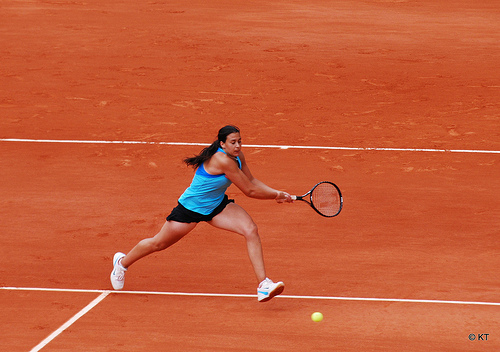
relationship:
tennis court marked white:
[1, 0, 496, 350] [3, 132, 495, 350]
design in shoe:
[257, 287, 268, 295] [252, 276, 284, 303]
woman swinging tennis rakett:
[110, 125, 283, 304] [270, 177, 347, 217]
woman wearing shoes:
[110, 125, 283, 304] [113, 247, 128, 290]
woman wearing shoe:
[110, 125, 283, 304] [254, 276, 285, 303]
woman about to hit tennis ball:
[107, 123, 297, 303] [311, 309, 326, 324]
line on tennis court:
[1, 136, 498, 153] [1, 0, 496, 350]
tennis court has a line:
[1, 0, 496, 350] [1, 136, 498, 153]